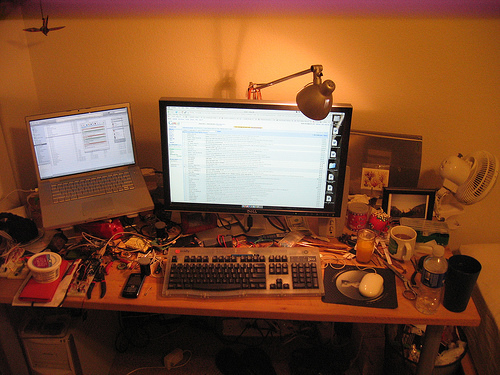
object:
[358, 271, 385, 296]
mouse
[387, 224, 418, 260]
white mug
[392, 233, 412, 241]
coffee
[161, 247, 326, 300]
keyboard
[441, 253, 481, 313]
cup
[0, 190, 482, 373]
desk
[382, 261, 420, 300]
scissors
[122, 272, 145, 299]
cell phone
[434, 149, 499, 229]
fan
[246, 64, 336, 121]
lamp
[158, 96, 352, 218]
monitor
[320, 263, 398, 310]
mousepad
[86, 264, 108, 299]
pliers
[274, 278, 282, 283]
keys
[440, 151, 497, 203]
back